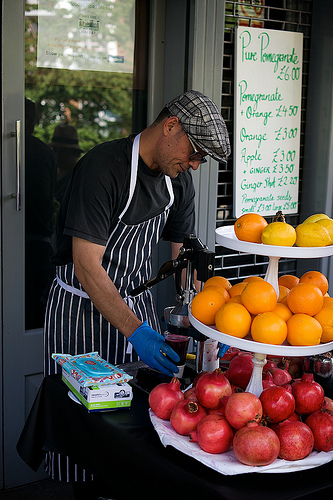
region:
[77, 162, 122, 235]
the shirt is black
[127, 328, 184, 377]
the glove is blue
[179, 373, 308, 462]
the pomogranites are red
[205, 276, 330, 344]
the oranges are on the second shelf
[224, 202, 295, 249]
the orange is beside the lemon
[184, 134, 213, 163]
the man is wearing sunglasses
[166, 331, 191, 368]
the man is holding a cup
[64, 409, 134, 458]
the table cloth is black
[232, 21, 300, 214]
the sign is white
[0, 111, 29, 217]
the handle is silver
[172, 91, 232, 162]
black and white pattern hat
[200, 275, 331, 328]
lots of oranges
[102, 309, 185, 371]
hand wearing a blue glove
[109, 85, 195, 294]
man working with fruit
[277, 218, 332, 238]
several yellow lemons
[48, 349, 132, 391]
moist wipes for cleaning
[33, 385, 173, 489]
black and white table cloth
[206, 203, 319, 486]
white stand with lots of fruit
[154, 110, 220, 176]
man wearing dark glasses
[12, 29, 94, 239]
glass door with handle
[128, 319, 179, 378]
a man wearing blue gloves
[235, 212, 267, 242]
a bright orange on the display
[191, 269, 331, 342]
oranges on the second display tray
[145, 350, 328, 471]
a pomegranate fruit on the bottom tray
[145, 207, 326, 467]
a center piece display tray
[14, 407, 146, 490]
a black vinyl table cloth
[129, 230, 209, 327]
a portable manual juicer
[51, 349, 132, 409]
a box of paper wipes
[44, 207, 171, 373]
a black and white striped apron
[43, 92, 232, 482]
Man making a juice drink.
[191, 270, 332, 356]
Oranges on middle tier.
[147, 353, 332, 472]
Pomegranates on the bottom plate.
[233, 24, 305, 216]
Menu in the window.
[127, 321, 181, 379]
Blue plastic glove on man's hand.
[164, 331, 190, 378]
Freshly-pressed purple juice drink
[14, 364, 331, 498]
Black tablecloth covering table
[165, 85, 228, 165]
Plaid hat on man's head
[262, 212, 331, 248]
Four lemons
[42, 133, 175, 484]
Black and white striped apron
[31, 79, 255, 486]
man wearing blue gloves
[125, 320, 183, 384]
a blue glove on a hand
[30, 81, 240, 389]
man wears an apron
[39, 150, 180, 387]
apron color white and black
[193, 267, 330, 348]
the oranges are in a container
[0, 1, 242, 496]
man is in front a door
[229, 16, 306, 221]
a white board on a window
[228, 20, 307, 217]
white board has green letters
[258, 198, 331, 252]
lemons on top a container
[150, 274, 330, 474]
red pomegranates below oranges